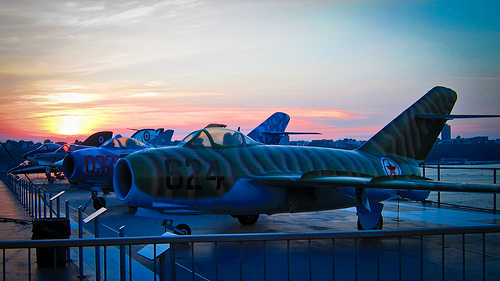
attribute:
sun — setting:
[45, 112, 102, 134]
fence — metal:
[0, 223, 500, 279]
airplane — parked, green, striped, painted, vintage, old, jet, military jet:
[113, 85, 499, 234]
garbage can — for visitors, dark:
[31, 216, 73, 266]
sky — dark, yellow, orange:
[0, 0, 500, 151]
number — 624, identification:
[164, 155, 227, 192]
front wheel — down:
[173, 224, 191, 235]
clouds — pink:
[0, 89, 380, 149]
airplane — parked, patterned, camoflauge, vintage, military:
[61, 128, 152, 211]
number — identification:
[85, 153, 125, 177]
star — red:
[384, 159, 398, 176]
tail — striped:
[354, 87, 458, 161]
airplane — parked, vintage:
[13, 142, 94, 183]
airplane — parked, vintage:
[21, 141, 63, 158]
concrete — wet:
[15, 173, 499, 280]